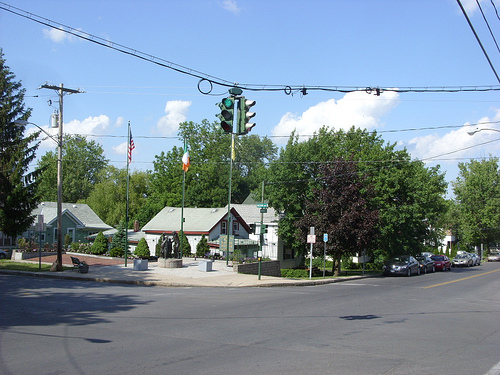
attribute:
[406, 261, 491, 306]
line — yellow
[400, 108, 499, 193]
cloud — white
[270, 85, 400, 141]
cloud — white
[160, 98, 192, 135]
cloud — white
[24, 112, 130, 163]
cloud — white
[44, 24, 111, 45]
cloud — white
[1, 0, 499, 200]
sky — blue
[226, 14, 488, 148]
sky — blue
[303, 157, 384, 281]
tree — purplish, green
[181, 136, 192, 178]
flag — green, orange, white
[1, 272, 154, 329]
shadow — tree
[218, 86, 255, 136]
stoplight — green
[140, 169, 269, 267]
white house — small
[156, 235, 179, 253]
statue — bronze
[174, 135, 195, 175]
flag — green, white, and orange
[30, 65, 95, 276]
pole — wooden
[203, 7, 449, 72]
sky — clear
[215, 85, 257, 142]
bright light — traffic, hanging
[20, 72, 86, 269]
post — wooden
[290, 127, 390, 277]
tree — different, variety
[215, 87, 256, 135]
lights — signal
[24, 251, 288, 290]
courtyard — small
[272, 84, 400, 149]
cloud — white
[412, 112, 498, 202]
cloud — white